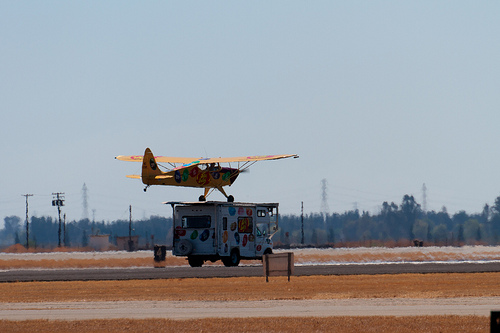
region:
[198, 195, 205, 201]
Wheel of glider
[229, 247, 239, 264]
wheel of truck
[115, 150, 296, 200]
yellow color glider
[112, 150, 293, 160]
wings of the glider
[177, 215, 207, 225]
window of the truck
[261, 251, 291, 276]
sign board near way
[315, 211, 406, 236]
trees at background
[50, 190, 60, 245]
poles erected at distance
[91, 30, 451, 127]
blue and clear sky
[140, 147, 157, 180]
rudder wings of the glider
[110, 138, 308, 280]
plane on top of a truck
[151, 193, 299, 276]
truck on the road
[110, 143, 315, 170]
large wings on top of the plane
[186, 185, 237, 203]
two wheels on the bottom of the train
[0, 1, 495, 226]
no clouds visible in the sky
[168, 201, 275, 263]
drawings all over the truck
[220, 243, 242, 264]
back wheel of the truck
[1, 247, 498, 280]
street is made of asphalt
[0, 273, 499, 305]
yellow grass on the ground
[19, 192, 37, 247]
tall and skinny pole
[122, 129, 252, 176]
small plane above truck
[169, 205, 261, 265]
colorful side of truck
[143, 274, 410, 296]
brown grass near runway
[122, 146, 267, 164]
orange wings on plane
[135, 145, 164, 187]
orange tail on plane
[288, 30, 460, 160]
blue and white sky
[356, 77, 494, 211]
no clouds in hazy sky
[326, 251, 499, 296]
runway is dark grey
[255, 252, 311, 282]
small sign near truck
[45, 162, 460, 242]
power lines in distance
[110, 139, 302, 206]
the plane is yellow.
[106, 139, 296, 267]
plane on top of the truck.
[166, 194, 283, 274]
stickers on the truck.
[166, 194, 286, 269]
the truck is white.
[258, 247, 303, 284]
sign in the ground.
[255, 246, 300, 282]
sign next to the truck.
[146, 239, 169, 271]
garbage can next to the truck.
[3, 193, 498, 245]
trees in the distance.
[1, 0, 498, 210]
the sky is blue.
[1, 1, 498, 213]
the sky is clear.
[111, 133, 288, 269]
plane on top of a truck.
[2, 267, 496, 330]
the ground is brown.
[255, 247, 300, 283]
sign in front of the truck.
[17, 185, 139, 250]
electricity poles behind the truck.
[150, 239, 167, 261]
trash can behind the truck.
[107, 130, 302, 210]
the plane is small.